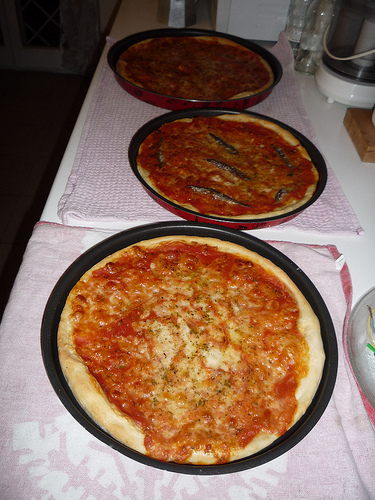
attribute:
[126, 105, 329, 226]
pizza pan — black, red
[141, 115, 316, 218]
pizza — cooked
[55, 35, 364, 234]
dish towel — pink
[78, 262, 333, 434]
pizza — cheese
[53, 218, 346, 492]
dish — black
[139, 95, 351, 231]
pizza — cooked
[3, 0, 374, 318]
counter — white 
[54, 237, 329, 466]
cheese pizza — whole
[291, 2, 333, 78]
bottle — clear, glass bottle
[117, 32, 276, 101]
pizza — cheese pizza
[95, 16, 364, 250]
table cloth — pink, white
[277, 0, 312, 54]
glass — tall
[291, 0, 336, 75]
glass — tall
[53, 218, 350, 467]
pizza — black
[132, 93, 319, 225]
pizza — sausage pizza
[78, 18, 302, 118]
dish — deep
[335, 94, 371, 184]
block — wooden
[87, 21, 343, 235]
pan — black, red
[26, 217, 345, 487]
pan — black